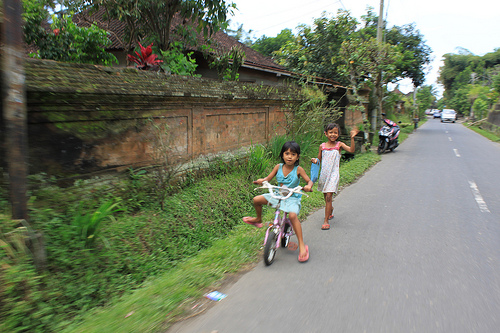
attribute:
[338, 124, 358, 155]
left arm — waving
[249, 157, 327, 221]
outfit — blue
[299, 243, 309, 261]
sandal — pink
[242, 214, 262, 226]
sandal — pink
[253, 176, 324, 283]
bicycle — pink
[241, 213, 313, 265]
flip flops — pink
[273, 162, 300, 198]
top — blue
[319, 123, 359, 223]
girl — waving at camera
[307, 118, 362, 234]
girl — smiling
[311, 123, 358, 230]
girl — walking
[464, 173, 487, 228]
line — white